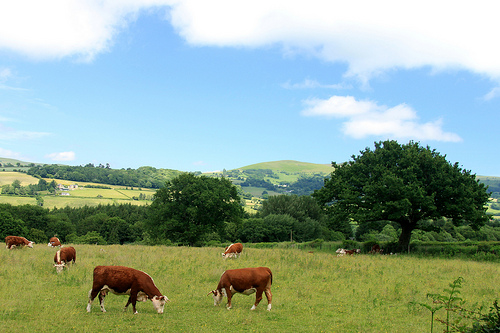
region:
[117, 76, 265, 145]
Bright blue skies from above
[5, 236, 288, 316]
A group of cows grazing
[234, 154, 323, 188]
A mountain in the background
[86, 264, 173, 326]
A brown and white cow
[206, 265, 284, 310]
A brown and white cow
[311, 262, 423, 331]
Light green grass on the field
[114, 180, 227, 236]
Trees in the distance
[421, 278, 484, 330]
Green weeds on the field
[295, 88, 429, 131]
White clouds in the sky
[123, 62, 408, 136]
Blue sky with white clouds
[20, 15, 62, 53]
white clouds in blue sky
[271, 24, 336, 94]
white clouds in blue sky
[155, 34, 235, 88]
white clouds in blue sky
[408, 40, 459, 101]
white clouds in blue sky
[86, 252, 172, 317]
brown cow grazing in field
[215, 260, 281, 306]
brown cow grazing in field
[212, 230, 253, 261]
brown cow grazing in field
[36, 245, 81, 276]
brown cow grazing in field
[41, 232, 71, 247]
brown cow grazing in field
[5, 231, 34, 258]
brown cow grazing in field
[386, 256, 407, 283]
green grass on ground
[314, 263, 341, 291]
green grass on ground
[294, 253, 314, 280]
green grass on ground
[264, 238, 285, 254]
green grass on ground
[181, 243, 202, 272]
green grass on ground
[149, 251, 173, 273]
green grass on ground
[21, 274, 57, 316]
green grass on ground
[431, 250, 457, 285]
green grass on ground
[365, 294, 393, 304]
green grass on ground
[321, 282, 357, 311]
green grass on ground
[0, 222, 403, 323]
Cow in a grassy pasture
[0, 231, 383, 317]
Cow in a grassy pasture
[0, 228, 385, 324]
Cow in a grassy pasture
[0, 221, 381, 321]
Cow in a grassy pasture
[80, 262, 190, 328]
cow grazing in field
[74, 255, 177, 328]
cow eating grass in field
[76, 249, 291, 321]
cows grazing next to each other in field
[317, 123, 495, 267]
tall tree in field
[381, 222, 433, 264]
tree trunk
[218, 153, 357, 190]
green hill in horizon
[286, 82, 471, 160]
white cloud in blue sky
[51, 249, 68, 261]
white stripe on cow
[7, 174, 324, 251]
row of trees and foliage